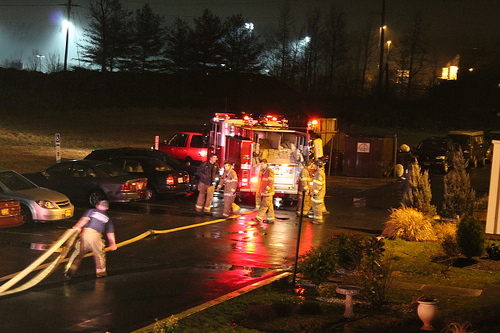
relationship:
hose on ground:
[105, 187, 237, 292] [137, 240, 195, 301]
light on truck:
[235, 143, 270, 207] [178, 72, 368, 229]